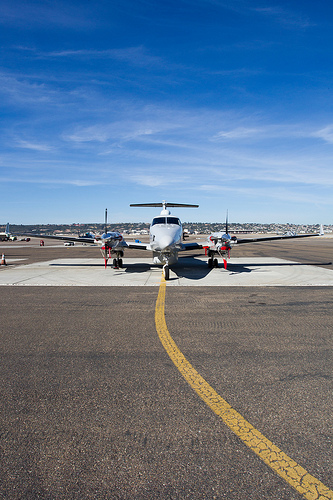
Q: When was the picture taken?
A: Daytime.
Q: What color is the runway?
A: Black.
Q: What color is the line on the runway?
A: Yellow.